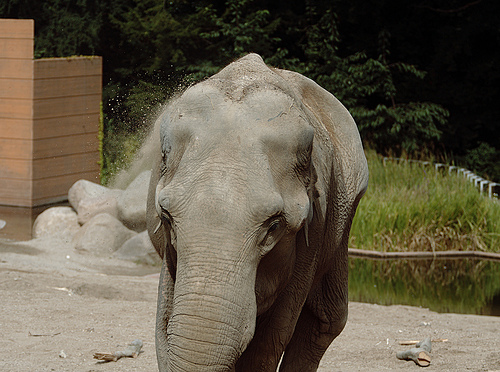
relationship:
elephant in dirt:
[126, 53, 373, 372] [301, 315, 461, 372]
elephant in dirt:
[126, 53, 373, 372] [63, 324, 483, 372]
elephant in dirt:
[126, 53, 373, 372] [30, 305, 482, 372]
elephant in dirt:
[126, 65, 342, 372] [18, 322, 497, 372]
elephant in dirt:
[126, 53, 373, 372] [24, 327, 493, 372]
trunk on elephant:
[155, 221, 253, 372] [143, 107, 312, 372]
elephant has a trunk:
[126, 53, 373, 372] [162, 242, 256, 368]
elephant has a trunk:
[126, 53, 373, 372] [123, 220, 285, 368]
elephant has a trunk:
[126, 53, 373, 372] [140, 231, 274, 370]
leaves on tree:
[366, 74, 447, 176] [341, 10, 487, 185]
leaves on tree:
[344, 16, 485, 196] [349, 20, 444, 148]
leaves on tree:
[298, 3, 441, 154] [336, 0, 477, 184]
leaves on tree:
[175, 0, 374, 80] [180, 0, 378, 80]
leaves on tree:
[88, 19, 240, 101] [120, 0, 260, 112]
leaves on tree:
[108, 5, 240, 100] [75, 9, 258, 100]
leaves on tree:
[0, 0, 146, 81] [3, 17, 153, 93]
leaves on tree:
[107, 0, 215, 100] [99, 0, 224, 87]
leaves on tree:
[143, 27, 255, 90] [78, 0, 344, 72]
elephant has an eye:
[126, 53, 373, 372] [245, 199, 297, 262]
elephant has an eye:
[126, 53, 373, 372] [245, 183, 310, 253]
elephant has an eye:
[126, 53, 373, 372] [246, 197, 302, 258]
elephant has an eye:
[126, 53, 373, 372] [234, 164, 297, 261]